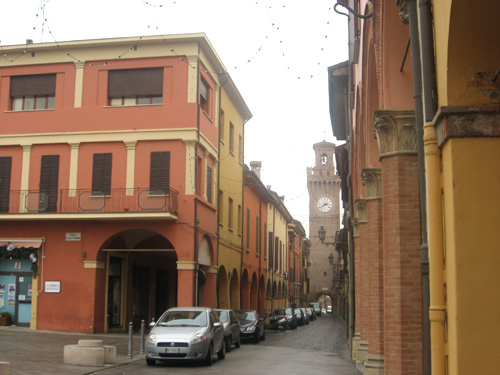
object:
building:
[0, 35, 200, 331]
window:
[102, 67, 165, 107]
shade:
[13, 76, 53, 95]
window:
[7, 77, 55, 112]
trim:
[0, 33, 222, 223]